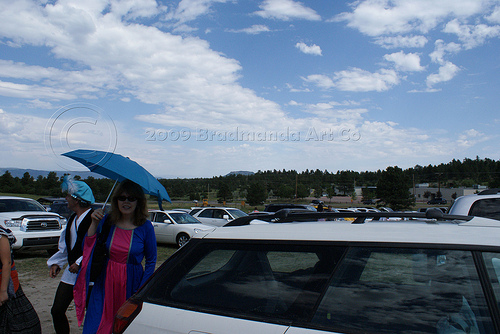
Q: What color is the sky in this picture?
A: Blue.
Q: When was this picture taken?
A: Daytime.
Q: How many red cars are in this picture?
A: Zero.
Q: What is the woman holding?
A: An Umbrella.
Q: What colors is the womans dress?
A: Blue and Pink.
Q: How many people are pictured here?
A: Three.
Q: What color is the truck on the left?
A: White.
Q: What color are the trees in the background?
A: Green.